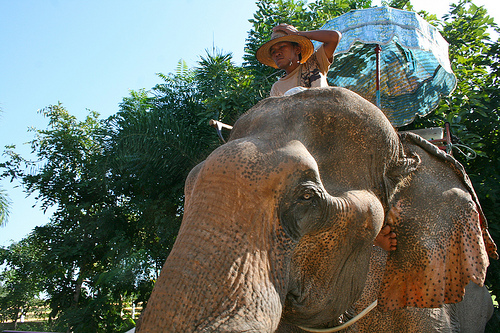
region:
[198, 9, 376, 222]
man riding an elephant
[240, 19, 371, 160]
man riding an elephant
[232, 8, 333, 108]
man riding an elephant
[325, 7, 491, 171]
the umbrella is blue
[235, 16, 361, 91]
Asian man wearing a straw type hat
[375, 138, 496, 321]
polka dot pattern on elephant's ear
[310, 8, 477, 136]
umbrella for shade on top of elephant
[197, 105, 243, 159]
tool resembling pick ax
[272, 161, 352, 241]
elephant eye with gray skin tone surrounding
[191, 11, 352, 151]
man holding on to hat on top of elephant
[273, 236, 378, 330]
sagging skin under elephant chin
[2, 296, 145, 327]
white wooden fence in background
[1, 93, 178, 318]
green leafy treed area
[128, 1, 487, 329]
elephant being used as tranportation by locals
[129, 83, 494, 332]
Elephant ridden by a man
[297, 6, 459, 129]
Blue umbrella on the back of the elephant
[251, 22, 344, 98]
Man holding his hat on top of the elephant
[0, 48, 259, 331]
Green tree leaves in the background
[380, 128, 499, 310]
Left ear of the elephant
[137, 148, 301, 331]
orange colored trunk of the elephant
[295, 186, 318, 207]
left eye of the elephant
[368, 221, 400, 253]
Bare foot of the man riding the elephant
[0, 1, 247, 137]
Clear blue sky in the background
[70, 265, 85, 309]
Brown trunk of a tree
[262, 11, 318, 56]
Person holding a hat on an elephant.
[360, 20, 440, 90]
Person holding a hat on an elephant.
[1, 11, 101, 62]
Person holding a hat on an elephant.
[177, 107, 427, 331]
this is an elephant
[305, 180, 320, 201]
this is the eye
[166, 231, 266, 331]
this is the trunk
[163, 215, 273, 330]
the trunk is long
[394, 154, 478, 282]
this is the ear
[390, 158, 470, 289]
the ear is big in color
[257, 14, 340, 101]
the man is on the back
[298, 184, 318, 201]
the eye is small in size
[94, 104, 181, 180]
these are the leaves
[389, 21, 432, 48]
this is an umbrella